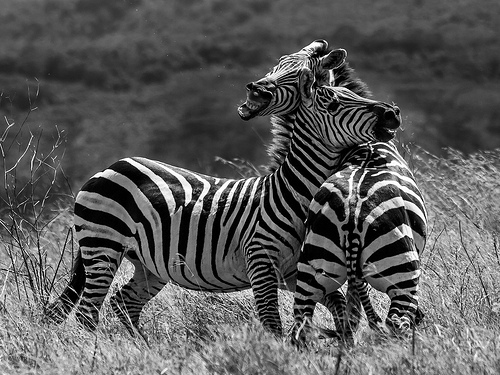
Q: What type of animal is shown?
A: Zebras.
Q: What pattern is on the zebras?
A: Stripes.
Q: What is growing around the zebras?
A: Tall grass.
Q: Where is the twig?
A: Behind zebra.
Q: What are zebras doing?
A: Fighting.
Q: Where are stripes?
A: On zebra.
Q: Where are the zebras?
A: In wild.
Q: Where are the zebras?
A: In field.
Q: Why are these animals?
A: Zebras.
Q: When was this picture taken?
A: Daytime.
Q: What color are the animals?
A: Black and White.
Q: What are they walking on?
A: Grass.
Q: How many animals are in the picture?
A: Two.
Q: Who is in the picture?
A: No one.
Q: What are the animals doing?
A: Fighting.